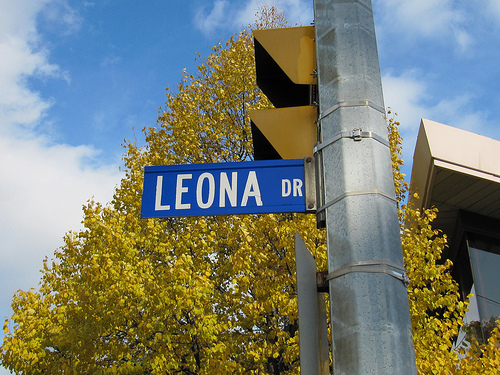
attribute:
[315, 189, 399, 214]
ring — metal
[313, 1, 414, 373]
post — grey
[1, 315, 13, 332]
leaf — yellow, small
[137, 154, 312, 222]
sign — blue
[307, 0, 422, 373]
metal — pole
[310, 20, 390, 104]
pole — discolored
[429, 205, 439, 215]
leaf — yellow, small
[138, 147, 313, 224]
sign — Leona Dr, street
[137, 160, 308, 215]
sign — street, blue, royal blue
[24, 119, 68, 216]
clouds — fluffy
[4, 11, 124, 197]
cloud — white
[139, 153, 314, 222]
street sign — blue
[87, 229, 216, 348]
elephant — yellow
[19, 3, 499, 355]
tree — yellow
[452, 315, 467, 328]
yellow leaf — small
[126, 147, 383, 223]
sign — blue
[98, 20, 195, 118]
sky — clear, blue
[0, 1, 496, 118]
sky — cloudy, blue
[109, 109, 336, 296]
sign — Leonia Dr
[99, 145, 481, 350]
sign — street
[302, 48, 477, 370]
pole — metal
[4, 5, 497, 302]
sky — partly cloudy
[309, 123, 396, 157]
band — steel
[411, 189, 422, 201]
leaf — small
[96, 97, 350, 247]
sign — street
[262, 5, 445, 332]
pole — metal